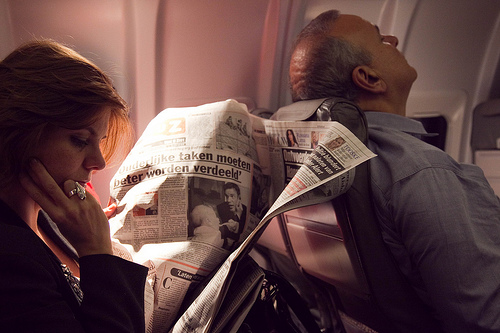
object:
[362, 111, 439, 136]
collar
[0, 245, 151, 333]
sleeve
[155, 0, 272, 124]
inside wall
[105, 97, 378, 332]
newspaper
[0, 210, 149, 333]
jacket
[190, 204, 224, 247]
baby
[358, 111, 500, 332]
shirt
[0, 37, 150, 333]
woman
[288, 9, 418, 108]
head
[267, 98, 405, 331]
chair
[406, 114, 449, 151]
windoe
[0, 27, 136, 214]
hair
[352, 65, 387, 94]
ear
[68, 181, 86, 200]
ring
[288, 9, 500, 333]
man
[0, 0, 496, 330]
airplane